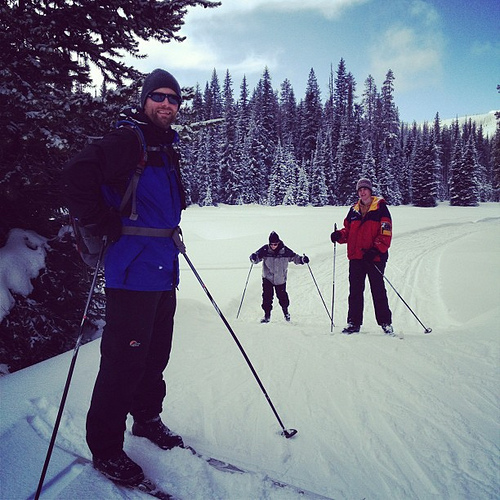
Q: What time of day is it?
A: Day time.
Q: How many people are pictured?
A: Three.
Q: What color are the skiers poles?
A: Black.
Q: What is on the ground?
A: Snow.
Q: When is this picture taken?
A: While skiing.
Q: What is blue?
A: Sky.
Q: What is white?
A: Snow.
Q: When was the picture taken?
A: Daytime.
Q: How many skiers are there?
A: 3.